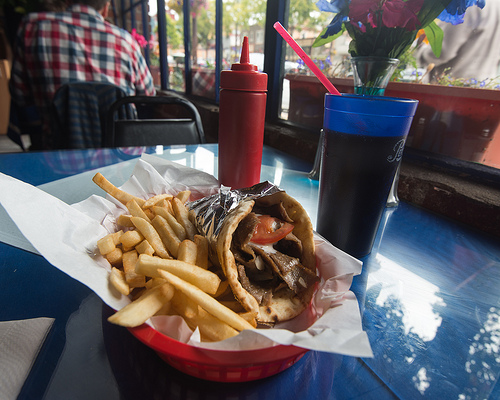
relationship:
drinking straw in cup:
[271, 20, 371, 134] [319, 90, 420, 282]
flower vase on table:
[351, 57, 398, 92] [5, 144, 495, 398]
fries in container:
[84, 165, 264, 343] [92, 186, 322, 385]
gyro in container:
[185, 181, 320, 329] [100, 184, 350, 387]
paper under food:
[0, 146, 381, 369] [82, 169, 330, 356]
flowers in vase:
[307, 2, 488, 64] [339, 54, 401, 97]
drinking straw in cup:
[271, 20, 371, 134] [321, 89, 420, 267]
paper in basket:
[0, 146, 381, 369] [100, 182, 349, 390]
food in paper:
[82, 169, 330, 356] [0, 146, 381, 369]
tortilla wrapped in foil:
[209, 186, 319, 327] [187, 178, 290, 247]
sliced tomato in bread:
[250, 216, 291, 242] [213, 187, 319, 322]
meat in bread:
[229, 198, 319, 302] [213, 187, 319, 322]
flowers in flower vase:
[307, 2, 488, 64] [351, 57, 398, 92]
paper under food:
[0, 146, 381, 369] [100, 160, 317, 354]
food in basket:
[82, 169, 330, 356] [128, 321, 310, 383]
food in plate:
[82, 169, 330, 356] [100, 304, 316, 398]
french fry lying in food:
[153, 266, 257, 332] [82, 169, 330, 356]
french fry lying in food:
[127, 214, 172, 258] [82, 169, 330, 356]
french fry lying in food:
[89, 168, 145, 205] [82, 169, 330, 356]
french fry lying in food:
[167, 193, 196, 238] [82, 169, 330, 356]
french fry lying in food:
[147, 211, 186, 252] [82, 169, 330, 356]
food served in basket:
[82, 169, 330, 356] [128, 321, 310, 383]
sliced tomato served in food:
[250, 216, 291, 242] [82, 169, 330, 356]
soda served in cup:
[315, 124, 406, 259] [315, 90, 418, 260]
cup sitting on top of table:
[315, 90, 418, 260] [5, 144, 495, 398]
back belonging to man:
[22, 11, 134, 146] [8, 1, 157, 151]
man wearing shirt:
[8, 1, 157, 151] [5, 5, 156, 148]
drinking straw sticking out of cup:
[271, 20, 371, 134] [315, 90, 418, 260]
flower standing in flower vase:
[315, 0, 351, 29] [351, 57, 398, 92]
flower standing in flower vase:
[345, 0, 381, 32] [351, 57, 398, 92]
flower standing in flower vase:
[379, 1, 425, 34] [351, 57, 398, 92]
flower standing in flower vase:
[439, 0, 484, 25] [351, 57, 398, 92]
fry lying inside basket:
[131, 250, 221, 294] [128, 321, 310, 383]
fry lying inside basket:
[153, 265, 253, 332] [128, 321, 310, 383]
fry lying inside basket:
[103, 279, 175, 329] [128, 321, 310, 383]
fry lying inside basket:
[91, 170, 145, 206] [128, 321, 310, 383]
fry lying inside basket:
[169, 195, 197, 238] [128, 321, 310, 383]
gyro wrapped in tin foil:
[185, 181, 320, 329] [183, 180, 287, 257]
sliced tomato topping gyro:
[250, 216, 291, 242] [185, 181, 320, 329]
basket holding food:
[128, 321, 310, 383] [82, 169, 330, 356]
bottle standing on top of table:
[214, 32, 271, 191] [5, 144, 495, 398]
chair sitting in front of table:
[101, 92, 207, 146] [5, 144, 495, 398]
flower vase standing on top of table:
[351, 57, 398, 92] [5, 144, 495, 398]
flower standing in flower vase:
[349, 0, 381, 33] [351, 57, 398, 92]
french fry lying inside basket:
[131, 249, 221, 295] [128, 321, 310, 383]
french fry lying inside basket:
[153, 266, 257, 332] [128, 321, 310, 383]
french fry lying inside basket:
[104, 278, 174, 329] [128, 321, 310, 383]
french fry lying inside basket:
[109, 263, 131, 295] [128, 321, 310, 383]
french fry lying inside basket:
[127, 214, 172, 258] [128, 321, 310, 383]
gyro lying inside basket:
[185, 181, 320, 329] [128, 321, 310, 383]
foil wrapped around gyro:
[185, 178, 285, 265] [185, 181, 320, 329]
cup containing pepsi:
[315, 90, 418, 260] [315, 125, 407, 259]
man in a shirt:
[8, 1, 157, 151] [5, 3, 158, 134]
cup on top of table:
[315, 90, 418, 260] [5, 144, 495, 398]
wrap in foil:
[189, 179, 319, 325] [185, 178, 285, 265]